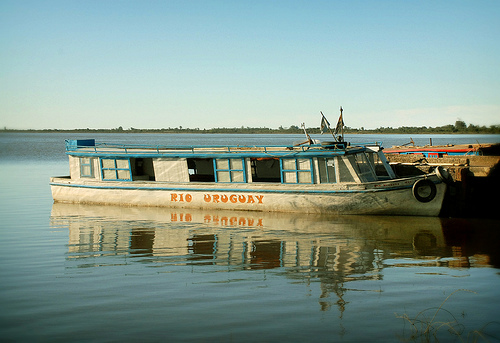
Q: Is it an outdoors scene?
A: Yes, it is outdoors.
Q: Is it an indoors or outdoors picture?
A: It is outdoors.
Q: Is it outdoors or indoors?
A: It is outdoors.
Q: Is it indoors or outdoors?
A: It is outdoors.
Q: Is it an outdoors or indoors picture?
A: It is outdoors.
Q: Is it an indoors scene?
A: No, it is outdoors.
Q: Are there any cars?
A: No, there are no cars.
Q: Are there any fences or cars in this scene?
A: No, there are no cars or fences.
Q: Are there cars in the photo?
A: No, there are no cars.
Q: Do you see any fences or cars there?
A: No, there are no cars or fences.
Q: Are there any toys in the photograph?
A: No, there are no toys.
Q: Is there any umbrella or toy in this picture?
A: No, there are no toys or umbrellas.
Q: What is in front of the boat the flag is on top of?
A: The life preserver is in front of the boat.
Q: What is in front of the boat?
A: The life preserver is in front of the boat.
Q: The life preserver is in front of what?
A: The life preserver is in front of the boat.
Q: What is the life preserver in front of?
A: The life preserver is in front of the boat.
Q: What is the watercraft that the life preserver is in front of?
A: The watercraft is a boat.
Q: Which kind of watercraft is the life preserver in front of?
A: The life preserver is in front of the boat.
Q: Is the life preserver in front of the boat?
A: Yes, the life preserver is in front of the boat.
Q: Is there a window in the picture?
A: Yes, there is a window.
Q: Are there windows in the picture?
A: Yes, there is a window.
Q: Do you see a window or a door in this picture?
A: Yes, there is a window.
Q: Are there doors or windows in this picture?
A: Yes, there is a window.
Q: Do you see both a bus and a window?
A: No, there is a window but no buses.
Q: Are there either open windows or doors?
A: Yes, there is an open window.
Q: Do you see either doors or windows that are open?
A: Yes, the window is open.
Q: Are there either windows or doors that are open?
A: Yes, the window is open.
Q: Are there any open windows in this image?
A: Yes, there is an open window.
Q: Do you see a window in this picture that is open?
A: Yes, there is a window that is open.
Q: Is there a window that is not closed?
A: Yes, there is a open window.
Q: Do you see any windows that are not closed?
A: Yes, there is a open window.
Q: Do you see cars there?
A: No, there are no cars.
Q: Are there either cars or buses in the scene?
A: No, there are no cars or buses.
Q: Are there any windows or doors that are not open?
A: No, there is a window but it is open.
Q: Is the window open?
A: Yes, the window is open.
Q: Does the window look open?
A: Yes, the window is open.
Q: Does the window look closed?
A: No, the window is open.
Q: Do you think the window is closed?
A: No, the window is open.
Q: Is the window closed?
A: No, the window is open.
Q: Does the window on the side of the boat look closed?
A: No, the window is open.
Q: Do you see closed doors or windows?
A: No, there is a window but it is open.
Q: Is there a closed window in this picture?
A: No, there is a window but it is open.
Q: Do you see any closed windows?
A: No, there is a window but it is open.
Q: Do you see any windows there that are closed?
A: No, there is a window but it is open.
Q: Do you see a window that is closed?
A: No, there is a window but it is open.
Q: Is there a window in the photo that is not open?
A: No, there is a window but it is open.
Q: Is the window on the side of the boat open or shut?
A: The window is open.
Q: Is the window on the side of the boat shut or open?
A: The window is open.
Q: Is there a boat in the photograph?
A: Yes, there is a boat.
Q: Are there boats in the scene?
A: Yes, there is a boat.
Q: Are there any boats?
A: Yes, there is a boat.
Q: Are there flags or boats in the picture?
A: Yes, there is a boat.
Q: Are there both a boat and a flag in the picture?
A: Yes, there are both a boat and a flag.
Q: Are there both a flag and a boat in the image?
A: Yes, there are both a boat and a flag.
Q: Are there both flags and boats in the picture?
A: Yes, there are both a boat and a flag.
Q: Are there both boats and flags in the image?
A: Yes, there are both a boat and a flag.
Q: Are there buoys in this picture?
A: No, there are no buoys.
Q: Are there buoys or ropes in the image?
A: No, there are no buoys or ropes.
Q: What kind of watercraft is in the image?
A: The watercraft is a boat.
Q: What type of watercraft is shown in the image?
A: The watercraft is a boat.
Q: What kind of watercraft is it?
A: The watercraft is a boat.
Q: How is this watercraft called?
A: This is a boat.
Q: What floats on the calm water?
A: The boat floats on the water.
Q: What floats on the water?
A: The boat floats on the water.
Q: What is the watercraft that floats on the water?
A: The watercraft is a boat.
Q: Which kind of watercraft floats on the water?
A: The watercraft is a boat.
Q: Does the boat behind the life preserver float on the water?
A: Yes, the boat floats on the water.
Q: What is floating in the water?
A: The boat is floating in the water.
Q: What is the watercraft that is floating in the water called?
A: The watercraft is a boat.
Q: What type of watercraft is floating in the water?
A: The watercraft is a boat.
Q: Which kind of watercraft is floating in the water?
A: The watercraft is a boat.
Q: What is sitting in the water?
A: The boat is sitting in the water.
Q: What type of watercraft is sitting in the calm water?
A: The watercraft is a boat.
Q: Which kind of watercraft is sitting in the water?
A: The watercraft is a boat.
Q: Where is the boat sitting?
A: The boat is sitting in the water.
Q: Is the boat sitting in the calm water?
A: Yes, the boat is sitting in the water.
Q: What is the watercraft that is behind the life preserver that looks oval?
A: The watercraft is a boat.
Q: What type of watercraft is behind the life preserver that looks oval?
A: The watercraft is a boat.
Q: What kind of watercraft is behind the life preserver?
A: The watercraft is a boat.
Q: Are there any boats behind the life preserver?
A: Yes, there is a boat behind the life preserver.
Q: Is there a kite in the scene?
A: No, there are no kites.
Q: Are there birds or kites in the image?
A: No, there are no kites or birds.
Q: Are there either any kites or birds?
A: No, there are no kites or birds.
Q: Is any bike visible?
A: No, there are no bikes.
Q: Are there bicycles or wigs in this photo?
A: No, there are no bicycles or wigs.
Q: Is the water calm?
A: Yes, the water is calm.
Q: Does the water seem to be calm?
A: Yes, the water is calm.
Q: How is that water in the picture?
A: The water is calm.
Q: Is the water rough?
A: No, the water is calm.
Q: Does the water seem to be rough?
A: No, the water is calm.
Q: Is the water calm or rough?
A: The water is calm.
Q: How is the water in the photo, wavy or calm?
A: The water is calm.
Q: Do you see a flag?
A: Yes, there is a flag.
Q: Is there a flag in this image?
A: Yes, there is a flag.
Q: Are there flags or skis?
A: Yes, there is a flag.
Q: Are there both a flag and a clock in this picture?
A: No, there is a flag but no clocks.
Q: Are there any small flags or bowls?
A: Yes, there is a small flag.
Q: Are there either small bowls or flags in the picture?
A: Yes, there is a small flag.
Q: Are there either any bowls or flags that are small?
A: Yes, the flag is small.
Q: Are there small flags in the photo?
A: Yes, there is a small flag.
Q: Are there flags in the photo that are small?
A: Yes, there is a flag that is small.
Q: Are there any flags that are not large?
A: Yes, there is a small flag.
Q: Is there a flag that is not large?
A: Yes, there is a small flag.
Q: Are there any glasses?
A: No, there are no glasses.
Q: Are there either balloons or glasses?
A: No, there are no glasses or balloons.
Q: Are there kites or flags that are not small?
A: No, there is a flag but it is small.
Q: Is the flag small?
A: Yes, the flag is small.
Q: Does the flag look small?
A: Yes, the flag is small.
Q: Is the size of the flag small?
A: Yes, the flag is small.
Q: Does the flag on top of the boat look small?
A: Yes, the flag is small.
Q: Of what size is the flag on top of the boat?
A: The flag is small.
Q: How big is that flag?
A: The flag is small.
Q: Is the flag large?
A: No, the flag is small.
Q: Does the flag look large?
A: No, the flag is small.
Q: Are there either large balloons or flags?
A: No, there is a flag but it is small.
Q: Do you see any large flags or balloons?
A: No, there is a flag but it is small.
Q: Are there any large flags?
A: No, there is a flag but it is small.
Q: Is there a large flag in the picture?
A: No, there is a flag but it is small.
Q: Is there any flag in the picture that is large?
A: No, there is a flag but it is small.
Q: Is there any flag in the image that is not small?
A: No, there is a flag but it is small.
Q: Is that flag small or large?
A: The flag is small.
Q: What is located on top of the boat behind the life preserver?
A: The flag is on top of the boat.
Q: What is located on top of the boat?
A: The flag is on top of the boat.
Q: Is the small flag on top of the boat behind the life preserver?
A: Yes, the flag is on top of the boat.